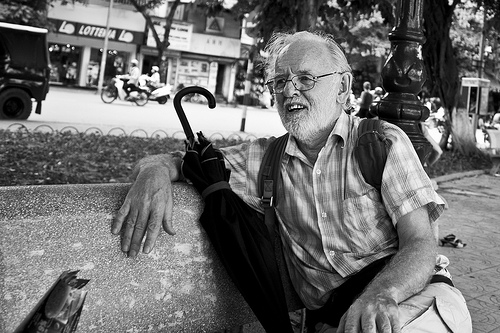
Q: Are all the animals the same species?
A: Yes, all the animals are birds.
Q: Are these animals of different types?
A: No, all the animals are birds.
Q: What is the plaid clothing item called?
A: The clothing item is a shirt.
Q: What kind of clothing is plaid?
A: The clothing is a shirt.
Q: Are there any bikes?
A: Yes, there are bikes.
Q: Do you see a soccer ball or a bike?
A: Yes, there are bikes.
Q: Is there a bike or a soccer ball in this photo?
A: Yes, there are bikes.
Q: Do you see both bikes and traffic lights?
A: No, there are bikes but no traffic lights.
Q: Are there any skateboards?
A: No, there are no skateboards.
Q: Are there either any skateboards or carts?
A: No, there are no skateboards or carts.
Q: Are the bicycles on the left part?
A: Yes, the bicycles are on the left of the image.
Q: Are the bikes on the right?
A: No, the bikes are on the left of the image.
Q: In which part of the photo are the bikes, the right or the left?
A: The bikes are on the left of the image.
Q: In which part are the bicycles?
A: The bicycles are on the left of the image.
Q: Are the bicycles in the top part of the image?
A: Yes, the bicycles are in the top of the image.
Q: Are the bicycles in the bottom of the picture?
A: No, the bicycles are in the top of the image.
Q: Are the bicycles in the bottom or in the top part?
A: The bicycles are in the top of the image.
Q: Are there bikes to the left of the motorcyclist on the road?
A: Yes, there are bikes to the left of the motorcyclist.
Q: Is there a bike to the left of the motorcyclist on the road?
A: Yes, there are bikes to the left of the motorcyclist.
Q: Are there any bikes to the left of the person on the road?
A: Yes, there are bikes to the left of the motorcyclist.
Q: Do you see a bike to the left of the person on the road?
A: Yes, there are bikes to the left of the motorcyclist.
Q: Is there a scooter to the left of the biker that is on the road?
A: No, there are bikes to the left of the biker.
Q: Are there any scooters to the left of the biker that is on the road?
A: No, there are bikes to the left of the biker.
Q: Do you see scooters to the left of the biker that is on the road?
A: No, there are bikes to the left of the biker.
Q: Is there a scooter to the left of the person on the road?
A: No, there are bikes to the left of the biker.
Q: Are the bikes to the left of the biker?
A: Yes, the bikes are to the left of the biker.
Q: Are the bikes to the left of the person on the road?
A: Yes, the bikes are to the left of the biker.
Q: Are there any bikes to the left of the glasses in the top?
A: Yes, there are bikes to the left of the glasses.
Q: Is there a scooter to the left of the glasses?
A: No, there are bikes to the left of the glasses.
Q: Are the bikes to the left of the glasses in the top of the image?
A: Yes, the bikes are to the left of the glasses.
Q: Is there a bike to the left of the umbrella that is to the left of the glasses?
A: Yes, there are bikes to the left of the umbrella.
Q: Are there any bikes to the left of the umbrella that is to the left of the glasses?
A: Yes, there are bikes to the left of the umbrella.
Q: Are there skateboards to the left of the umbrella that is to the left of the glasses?
A: No, there are bikes to the left of the umbrella.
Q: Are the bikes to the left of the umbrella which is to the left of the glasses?
A: Yes, the bikes are to the left of the umbrella.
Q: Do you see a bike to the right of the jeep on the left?
A: Yes, there are bikes to the right of the jeep.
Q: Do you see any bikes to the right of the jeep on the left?
A: Yes, there are bikes to the right of the jeep.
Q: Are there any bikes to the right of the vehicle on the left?
A: Yes, there are bikes to the right of the jeep.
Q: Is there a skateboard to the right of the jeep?
A: No, there are bikes to the right of the jeep.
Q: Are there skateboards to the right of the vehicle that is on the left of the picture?
A: No, there are bikes to the right of the jeep.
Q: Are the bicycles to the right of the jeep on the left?
A: Yes, the bicycles are to the right of the jeep.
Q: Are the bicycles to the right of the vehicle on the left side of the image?
A: Yes, the bicycles are to the right of the jeep.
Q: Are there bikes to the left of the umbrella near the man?
A: Yes, there are bikes to the left of the umbrella.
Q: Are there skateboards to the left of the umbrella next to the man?
A: No, there are bikes to the left of the umbrella.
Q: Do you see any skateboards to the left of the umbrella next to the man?
A: No, there are bikes to the left of the umbrella.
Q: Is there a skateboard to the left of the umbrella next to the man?
A: No, there are bikes to the left of the umbrella.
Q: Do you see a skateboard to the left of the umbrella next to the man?
A: No, there are bikes to the left of the umbrella.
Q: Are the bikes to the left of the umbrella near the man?
A: Yes, the bikes are to the left of the umbrella.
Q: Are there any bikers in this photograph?
A: Yes, there is a biker.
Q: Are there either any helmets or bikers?
A: Yes, there is a biker.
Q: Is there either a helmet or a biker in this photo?
A: Yes, there is a biker.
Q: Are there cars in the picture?
A: No, there are no cars.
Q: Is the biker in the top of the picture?
A: Yes, the biker is in the top of the image.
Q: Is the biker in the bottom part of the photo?
A: No, the biker is in the top of the image.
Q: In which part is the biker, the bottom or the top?
A: The biker is in the top of the image.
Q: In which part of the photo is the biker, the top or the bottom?
A: The biker is in the top of the image.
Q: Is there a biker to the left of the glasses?
A: Yes, there is a biker to the left of the glasses.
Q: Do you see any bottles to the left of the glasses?
A: No, there is a biker to the left of the glasses.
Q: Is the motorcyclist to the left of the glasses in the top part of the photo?
A: Yes, the motorcyclist is to the left of the glasses.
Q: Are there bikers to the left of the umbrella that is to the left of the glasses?
A: Yes, there is a biker to the left of the umbrella.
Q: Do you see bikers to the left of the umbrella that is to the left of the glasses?
A: Yes, there is a biker to the left of the umbrella.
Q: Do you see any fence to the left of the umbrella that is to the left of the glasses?
A: No, there is a biker to the left of the umbrella.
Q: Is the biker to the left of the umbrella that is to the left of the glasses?
A: Yes, the biker is to the left of the umbrella.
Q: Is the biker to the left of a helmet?
A: No, the biker is to the left of the umbrella.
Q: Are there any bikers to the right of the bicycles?
A: Yes, there is a biker to the right of the bicycles.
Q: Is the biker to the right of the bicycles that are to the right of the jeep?
A: Yes, the biker is to the right of the bicycles.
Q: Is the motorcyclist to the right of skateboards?
A: No, the motorcyclist is to the right of the bicycles.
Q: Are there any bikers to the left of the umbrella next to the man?
A: Yes, there is a biker to the left of the umbrella.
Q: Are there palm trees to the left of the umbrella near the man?
A: No, there is a biker to the left of the umbrella.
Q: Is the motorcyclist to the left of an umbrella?
A: Yes, the motorcyclist is to the left of an umbrella.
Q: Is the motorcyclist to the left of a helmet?
A: No, the motorcyclist is to the left of an umbrella.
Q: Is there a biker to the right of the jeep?
A: Yes, there is a biker to the right of the jeep.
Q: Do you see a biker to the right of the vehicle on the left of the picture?
A: Yes, there is a biker to the right of the jeep.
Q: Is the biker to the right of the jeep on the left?
A: Yes, the biker is to the right of the jeep.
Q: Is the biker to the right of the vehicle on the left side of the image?
A: Yes, the biker is to the right of the jeep.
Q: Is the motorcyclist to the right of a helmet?
A: No, the motorcyclist is to the right of the jeep.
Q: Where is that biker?
A: The biker is on the road.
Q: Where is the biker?
A: The biker is on the road.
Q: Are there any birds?
A: Yes, there are birds.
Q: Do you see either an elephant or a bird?
A: Yes, there are birds.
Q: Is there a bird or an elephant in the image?
A: Yes, there are birds.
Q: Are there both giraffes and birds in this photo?
A: No, there are birds but no giraffes.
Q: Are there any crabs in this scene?
A: No, there are no crabs.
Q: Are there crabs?
A: No, there are no crabs.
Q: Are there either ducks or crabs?
A: No, there are no crabs or ducks.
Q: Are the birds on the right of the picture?
A: Yes, the birds are on the right of the image.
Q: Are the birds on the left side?
A: No, the birds are on the right of the image.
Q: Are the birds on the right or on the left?
A: The birds are on the right of the image.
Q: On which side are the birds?
A: The birds are on the right of the image.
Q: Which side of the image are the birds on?
A: The birds are on the right of the image.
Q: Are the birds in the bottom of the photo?
A: Yes, the birds are in the bottom of the image.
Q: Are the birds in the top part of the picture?
A: No, the birds are in the bottom of the image.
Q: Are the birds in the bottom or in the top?
A: The birds are in the bottom of the image.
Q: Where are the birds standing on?
A: The birds are standing on the sidewalk.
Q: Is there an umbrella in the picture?
A: Yes, there is an umbrella.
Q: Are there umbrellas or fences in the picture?
A: Yes, there is an umbrella.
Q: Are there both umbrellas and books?
A: No, there is an umbrella but no books.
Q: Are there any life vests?
A: No, there are no life vests.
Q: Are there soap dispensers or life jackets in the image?
A: No, there are no life jackets or soap dispensers.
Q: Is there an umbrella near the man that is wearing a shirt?
A: Yes, there is an umbrella near the man.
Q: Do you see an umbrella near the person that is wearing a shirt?
A: Yes, there is an umbrella near the man.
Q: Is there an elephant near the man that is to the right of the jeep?
A: No, there is an umbrella near the man.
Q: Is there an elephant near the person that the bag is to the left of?
A: No, there is an umbrella near the man.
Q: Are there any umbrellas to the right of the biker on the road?
A: Yes, there is an umbrella to the right of the motorcyclist.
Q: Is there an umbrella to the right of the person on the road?
A: Yes, there is an umbrella to the right of the motorcyclist.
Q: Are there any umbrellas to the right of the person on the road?
A: Yes, there is an umbrella to the right of the motorcyclist.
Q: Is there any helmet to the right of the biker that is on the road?
A: No, there is an umbrella to the right of the biker.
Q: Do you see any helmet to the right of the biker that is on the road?
A: No, there is an umbrella to the right of the biker.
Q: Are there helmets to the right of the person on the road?
A: No, there is an umbrella to the right of the biker.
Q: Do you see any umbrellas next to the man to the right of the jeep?
A: Yes, there is an umbrella next to the man.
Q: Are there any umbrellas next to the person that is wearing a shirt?
A: Yes, there is an umbrella next to the man.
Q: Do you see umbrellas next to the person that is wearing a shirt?
A: Yes, there is an umbrella next to the man.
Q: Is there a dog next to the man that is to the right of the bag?
A: No, there is an umbrella next to the man.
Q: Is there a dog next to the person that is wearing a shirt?
A: No, there is an umbrella next to the man.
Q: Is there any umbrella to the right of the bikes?
A: Yes, there is an umbrella to the right of the bikes.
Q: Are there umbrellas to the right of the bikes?
A: Yes, there is an umbrella to the right of the bikes.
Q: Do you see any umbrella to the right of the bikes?
A: Yes, there is an umbrella to the right of the bikes.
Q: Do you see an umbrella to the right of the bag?
A: Yes, there is an umbrella to the right of the bag.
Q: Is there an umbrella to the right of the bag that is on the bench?
A: Yes, there is an umbrella to the right of the bag.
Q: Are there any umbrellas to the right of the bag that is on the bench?
A: Yes, there is an umbrella to the right of the bag.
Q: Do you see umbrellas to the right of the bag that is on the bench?
A: Yes, there is an umbrella to the right of the bag.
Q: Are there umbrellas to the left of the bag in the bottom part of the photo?
A: No, the umbrella is to the right of the bag.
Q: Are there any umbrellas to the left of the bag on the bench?
A: No, the umbrella is to the right of the bag.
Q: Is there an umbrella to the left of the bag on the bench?
A: No, the umbrella is to the right of the bag.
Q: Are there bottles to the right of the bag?
A: No, there is an umbrella to the right of the bag.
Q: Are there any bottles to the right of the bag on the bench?
A: No, there is an umbrella to the right of the bag.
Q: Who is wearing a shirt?
A: The man is wearing a shirt.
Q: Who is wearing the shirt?
A: The man is wearing a shirt.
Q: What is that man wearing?
A: The man is wearing a shirt.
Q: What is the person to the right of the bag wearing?
A: The man is wearing a shirt.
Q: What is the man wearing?
A: The man is wearing a shirt.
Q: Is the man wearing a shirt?
A: Yes, the man is wearing a shirt.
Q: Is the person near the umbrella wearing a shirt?
A: Yes, the man is wearing a shirt.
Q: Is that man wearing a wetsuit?
A: No, the man is wearing a shirt.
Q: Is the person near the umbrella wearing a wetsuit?
A: No, the man is wearing a shirt.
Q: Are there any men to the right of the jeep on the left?
A: Yes, there is a man to the right of the jeep.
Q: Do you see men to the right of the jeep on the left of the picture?
A: Yes, there is a man to the right of the jeep.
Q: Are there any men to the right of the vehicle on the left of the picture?
A: Yes, there is a man to the right of the jeep.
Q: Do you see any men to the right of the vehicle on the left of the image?
A: Yes, there is a man to the right of the jeep.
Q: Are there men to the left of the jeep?
A: No, the man is to the right of the jeep.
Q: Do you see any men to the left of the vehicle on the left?
A: No, the man is to the right of the jeep.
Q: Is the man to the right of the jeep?
A: Yes, the man is to the right of the jeep.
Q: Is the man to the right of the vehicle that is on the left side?
A: Yes, the man is to the right of the jeep.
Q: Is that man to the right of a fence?
A: No, the man is to the right of the jeep.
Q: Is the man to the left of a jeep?
A: No, the man is to the right of a jeep.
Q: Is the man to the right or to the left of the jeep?
A: The man is to the right of the jeep.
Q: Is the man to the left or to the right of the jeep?
A: The man is to the right of the jeep.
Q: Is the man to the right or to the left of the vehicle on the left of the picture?
A: The man is to the right of the jeep.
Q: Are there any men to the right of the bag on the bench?
A: Yes, there is a man to the right of the bag.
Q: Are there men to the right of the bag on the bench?
A: Yes, there is a man to the right of the bag.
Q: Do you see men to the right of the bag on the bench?
A: Yes, there is a man to the right of the bag.